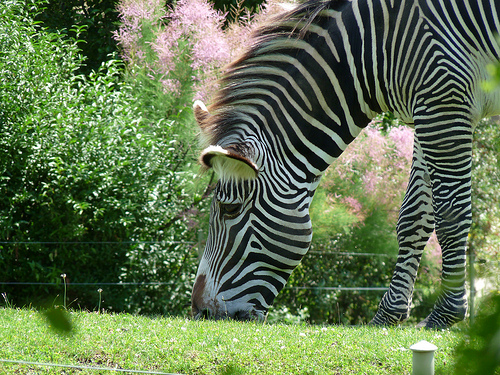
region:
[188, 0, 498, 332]
zebra grazing on the grass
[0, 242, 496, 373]
fence surrounding the zebra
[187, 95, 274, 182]
ears of the zebra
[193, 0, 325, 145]
mane of the zebra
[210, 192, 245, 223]
eye of the zebra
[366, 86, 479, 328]
legs of the zebra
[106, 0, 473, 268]
pink flowers on the bush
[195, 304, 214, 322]
nostrils of the zebra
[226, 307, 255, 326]
mouth of the zebra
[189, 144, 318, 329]
head of the zebra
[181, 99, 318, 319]
face of a zebra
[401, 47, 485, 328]
black and white zebra leg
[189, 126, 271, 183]
black and white zebra ear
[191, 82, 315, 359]
zebra grazing on grass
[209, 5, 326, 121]
mane on back of zebras neck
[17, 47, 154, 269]
leafy green shrubs in background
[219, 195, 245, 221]
black eye of zebra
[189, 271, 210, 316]
brown nose of zebra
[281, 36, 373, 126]
black and white stripes of zebra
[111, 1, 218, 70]
purple leaves of bush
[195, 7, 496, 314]
black and white striped zebra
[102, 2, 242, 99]
pink flower behind green bush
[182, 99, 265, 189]
ears on a striped zebra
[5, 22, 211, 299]
green bush in front of pink flower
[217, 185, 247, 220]
zebra's eye is open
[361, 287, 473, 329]
zebra's feet on ground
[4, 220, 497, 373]
wire fence around yard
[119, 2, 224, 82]
fuzzy pink flower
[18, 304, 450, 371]
green grass on ground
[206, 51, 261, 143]
brown mane on zebra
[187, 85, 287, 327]
the zebra is eating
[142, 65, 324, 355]
the zebra is eating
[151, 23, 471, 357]
black and white fur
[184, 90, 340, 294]
black and white fur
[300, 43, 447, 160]
black and white fur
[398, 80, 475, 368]
black and white fur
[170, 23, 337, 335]
zebra feeding on grass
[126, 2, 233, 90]
pink vegetation behind zebra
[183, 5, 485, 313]
white and black striped zebra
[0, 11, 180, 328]
green thick vegetation behind zebra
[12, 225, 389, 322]
meshed fence behind zebra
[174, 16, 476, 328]
zebra is looking down at grass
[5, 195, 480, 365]
zebra on grassy field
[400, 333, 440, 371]
white pole top with small cone on it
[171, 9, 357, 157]
zebra hair on top of head is thick and long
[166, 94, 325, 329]
zebra with brown nose